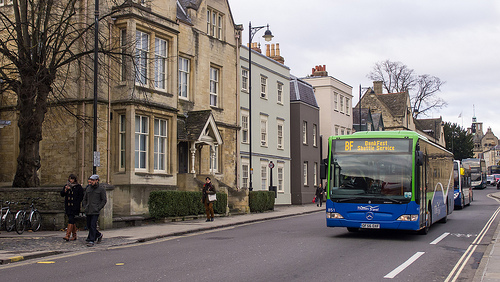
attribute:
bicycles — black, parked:
[0, 198, 43, 234]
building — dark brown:
[288, 77, 330, 212]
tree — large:
[3, 18, 100, 215]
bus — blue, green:
[328, 119, 473, 242]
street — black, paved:
[94, 127, 408, 280]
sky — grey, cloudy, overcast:
[228, 0, 498, 138]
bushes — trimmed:
[148, 191, 226, 215]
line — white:
[391, 252, 439, 259]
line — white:
[432, 230, 452, 248]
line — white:
[454, 251, 464, 264]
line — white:
[469, 245, 476, 258]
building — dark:
[292, 75, 324, 202]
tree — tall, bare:
[368, 61, 445, 132]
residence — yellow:
[6, 2, 246, 222]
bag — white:
[206, 193, 216, 203]